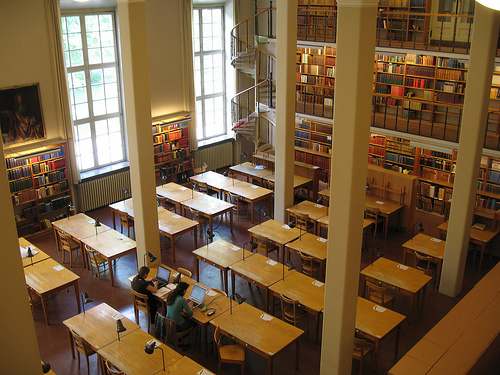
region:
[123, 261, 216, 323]
Two people doing research.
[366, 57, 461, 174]
Shelves of books fill the library.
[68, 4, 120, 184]
Long windows in the library.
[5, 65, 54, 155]
A painting on the wall.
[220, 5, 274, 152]
A lovely spiral staircase.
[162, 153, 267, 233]
Rows of empty desks.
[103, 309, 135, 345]
A lamp on the desk.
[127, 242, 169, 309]
A person working on a laptop.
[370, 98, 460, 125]
A railing on the second floor.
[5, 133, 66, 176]
Track lighting on the books.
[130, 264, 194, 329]
Two people sitting at a table in a library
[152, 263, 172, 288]
An open laptop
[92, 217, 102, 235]
A black lamp on top of a table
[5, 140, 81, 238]
A bookshelf full of books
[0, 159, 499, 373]
A bunch of tables in a library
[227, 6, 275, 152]
A winding staircase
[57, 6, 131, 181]
A tall window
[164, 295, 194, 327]
A green long sleeve shirt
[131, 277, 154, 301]
A short sleeve shirt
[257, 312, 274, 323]
A white rectangular object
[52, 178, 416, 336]
brown tables in hall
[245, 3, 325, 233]
white posts in hall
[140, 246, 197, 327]
people sitting at desk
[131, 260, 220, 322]
students sitting in front of laptops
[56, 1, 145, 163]
white frames on windows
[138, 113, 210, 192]
bookshelf near white windows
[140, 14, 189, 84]
white wall between windows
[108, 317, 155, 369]
black lights on desks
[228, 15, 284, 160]
spiral staircase near bookshelves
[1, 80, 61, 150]
picture on wall near window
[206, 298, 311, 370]
This is a table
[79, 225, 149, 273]
This is a table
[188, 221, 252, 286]
This is a table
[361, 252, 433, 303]
This is a table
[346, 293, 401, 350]
This is a table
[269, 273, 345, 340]
This is a table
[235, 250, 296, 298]
This is a table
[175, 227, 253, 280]
This is a table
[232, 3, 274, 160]
A metal, spiral staircase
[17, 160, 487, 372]
Wooden tables inside a library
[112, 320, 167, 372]
Lights on tables used for reading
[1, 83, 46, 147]
A Renaissance style painting on a wall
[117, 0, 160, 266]
A white support beam running from ground to ceiling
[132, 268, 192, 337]
People working at computers in a library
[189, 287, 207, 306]
A powered on laptop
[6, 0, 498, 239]
Shelves full of books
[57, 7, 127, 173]
A large window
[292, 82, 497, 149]
Wooden safety rails on the library scaffold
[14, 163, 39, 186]
Several books on shelves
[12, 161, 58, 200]
Several books on shelves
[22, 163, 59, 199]
Several books on shelves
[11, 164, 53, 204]
Several books on shelves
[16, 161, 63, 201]
Several books on shelves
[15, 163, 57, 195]
Several books on shelves